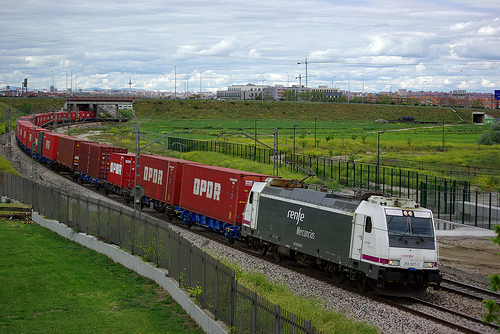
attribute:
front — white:
[374, 203, 444, 286]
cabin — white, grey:
[348, 191, 447, 289]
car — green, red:
[35, 130, 46, 156]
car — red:
[177, 158, 285, 230]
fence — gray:
[1, 163, 323, 334]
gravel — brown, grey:
[366, 305, 394, 322]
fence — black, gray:
[163, 133, 500, 237]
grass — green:
[132, 112, 500, 189]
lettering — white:
[281, 205, 308, 229]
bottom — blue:
[175, 207, 237, 236]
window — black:
[362, 213, 375, 235]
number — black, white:
[402, 261, 423, 268]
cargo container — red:
[39, 129, 71, 165]